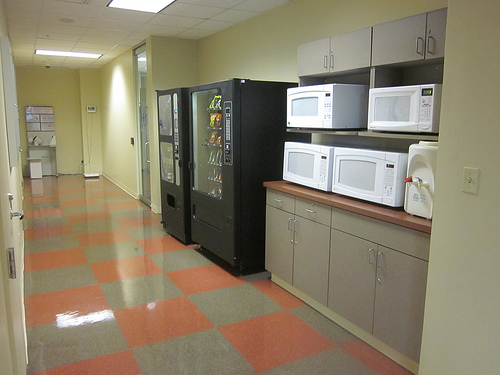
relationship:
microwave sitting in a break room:
[285, 79, 367, 131] [3, 2, 498, 375]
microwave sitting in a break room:
[368, 83, 439, 134] [3, 2, 498, 375]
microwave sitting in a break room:
[281, 139, 334, 193] [3, 2, 498, 375]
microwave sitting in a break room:
[330, 145, 409, 212] [3, 2, 498, 375]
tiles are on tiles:
[4, 1, 291, 71] [0, 0, 292, 71]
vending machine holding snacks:
[187, 78, 299, 278] [206, 92, 222, 197]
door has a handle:
[0, 17, 27, 359] [10, 207, 25, 220]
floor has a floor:
[23, 174, 418, 373] [23, 174, 418, 373]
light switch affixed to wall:
[462, 165, 481, 196] [419, 4, 499, 375]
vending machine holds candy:
[187, 78, 299, 278] [207, 150, 223, 199]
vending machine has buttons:
[187, 78, 299, 278] [224, 115, 231, 142]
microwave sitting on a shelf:
[285, 79, 367, 131] [286, 124, 363, 138]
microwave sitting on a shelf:
[368, 83, 439, 134] [358, 126, 438, 141]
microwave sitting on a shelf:
[281, 139, 334, 193] [265, 178, 431, 235]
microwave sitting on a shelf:
[330, 145, 409, 212] [286, 124, 363, 138]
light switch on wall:
[462, 165, 481, 196] [419, 4, 499, 375]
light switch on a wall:
[462, 165, 481, 196] [419, 4, 499, 375]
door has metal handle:
[0, 17, 27, 359] [10, 207, 25, 220]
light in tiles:
[33, 46, 103, 61] [0, 0, 292, 71]